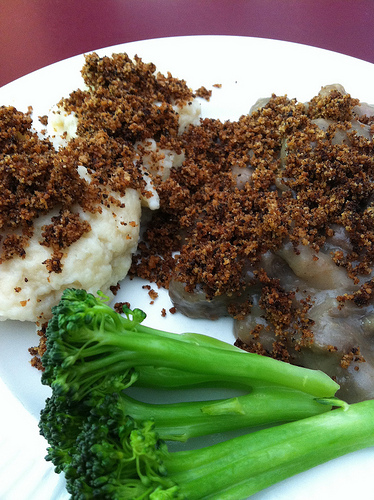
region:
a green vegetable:
[36, 289, 373, 498]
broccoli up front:
[36, 284, 372, 498]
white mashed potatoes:
[1, 51, 201, 318]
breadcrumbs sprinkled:
[0, 45, 371, 397]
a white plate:
[1, 32, 372, 498]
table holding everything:
[2, 3, 372, 495]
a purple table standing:
[2, 0, 372, 92]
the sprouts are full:
[35, 284, 169, 496]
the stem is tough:
[132, 320, 373, 498]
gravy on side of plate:
[170, 205, 373, 403]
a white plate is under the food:
[6, 33, 371, 498]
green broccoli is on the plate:
[39, 292, 372, 496]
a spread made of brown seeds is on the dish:
[2, 50, 369, 399]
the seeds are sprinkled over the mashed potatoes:
[0, 49, 197, 322]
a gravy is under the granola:
[188, 92, 372, 385]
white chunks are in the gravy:
[199, 82, 373, 378]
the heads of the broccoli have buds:
[32, 287, 135, 496]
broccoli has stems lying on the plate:
[154, 321, 373, 498]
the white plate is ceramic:
[4, 34, 373, 487]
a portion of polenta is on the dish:
[0, 92, 142, 318]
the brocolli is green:
[37, 287, 373, 498]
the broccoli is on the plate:
[40, 288, 371, 497]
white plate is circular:
[1, 34, 373, 497]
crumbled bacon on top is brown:
[0, 50, 372, 362]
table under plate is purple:
[0, 0, 372, 96]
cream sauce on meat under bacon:
[155, 81, 372, 404]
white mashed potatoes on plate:
[0, 98, 203, 322]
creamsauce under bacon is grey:
[152, 81, 373, 403]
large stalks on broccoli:
[131, 321, 371, 498]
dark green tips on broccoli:
[40, 287, 132, 499]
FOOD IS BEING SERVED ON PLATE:
[8, 35, 368, 269]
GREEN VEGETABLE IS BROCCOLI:
[21, 314, 370, 481]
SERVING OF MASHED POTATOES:
[12, 157, 144, 316]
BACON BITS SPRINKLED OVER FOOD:
[14, 56, 361, 276]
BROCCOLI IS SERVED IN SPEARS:
[27, 302, 352, 492]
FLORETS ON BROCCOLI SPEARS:
[34, 290, 166, 490]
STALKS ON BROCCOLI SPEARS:
[141, 317, 372, 492]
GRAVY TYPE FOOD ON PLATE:
[164, 244, 368, 400]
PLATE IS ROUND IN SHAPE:
[4, 29, 352, 173]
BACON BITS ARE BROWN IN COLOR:
[24, 77, 361, 289]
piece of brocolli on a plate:
[30, 286, 350, 446]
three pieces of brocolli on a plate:
[28, 283, 370, 496]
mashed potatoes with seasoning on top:
[0, 49, 162, 318]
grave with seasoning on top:
[148, 92, 373, 399]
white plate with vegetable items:
[4, 35, 372, 498]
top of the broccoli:
[30, 284, 186, 496]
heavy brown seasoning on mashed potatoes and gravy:
[7, 49, 369, 290]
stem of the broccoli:
[122, 303, 370, 498]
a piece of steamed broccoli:
[62, 394, 372, 497]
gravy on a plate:
[158, 92, 372, 400]